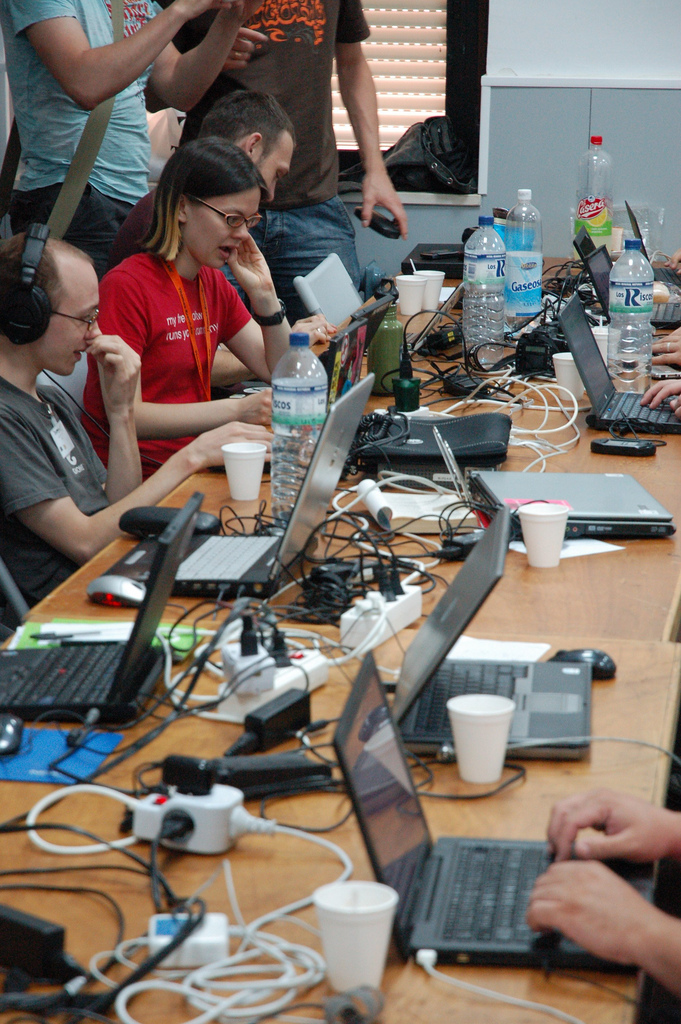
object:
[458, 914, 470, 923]
button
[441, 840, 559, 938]
keyboard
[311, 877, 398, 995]
styrofoam cup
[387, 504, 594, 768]
laptop computer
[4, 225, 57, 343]
headphones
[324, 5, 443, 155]
window blinds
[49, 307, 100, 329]
eyeglasses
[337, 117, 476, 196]
bag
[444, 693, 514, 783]
styrofoam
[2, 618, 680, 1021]
table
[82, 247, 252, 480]
tee shirt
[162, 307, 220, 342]
print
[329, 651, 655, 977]
computer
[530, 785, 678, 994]
man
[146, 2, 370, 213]
shirt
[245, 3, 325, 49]
design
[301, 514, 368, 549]
cords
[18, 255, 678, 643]
table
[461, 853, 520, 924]
keys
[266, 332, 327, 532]
water bottle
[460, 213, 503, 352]
water bottle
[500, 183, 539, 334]
water bottle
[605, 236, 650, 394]
water bottle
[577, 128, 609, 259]
water bottle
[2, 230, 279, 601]
person